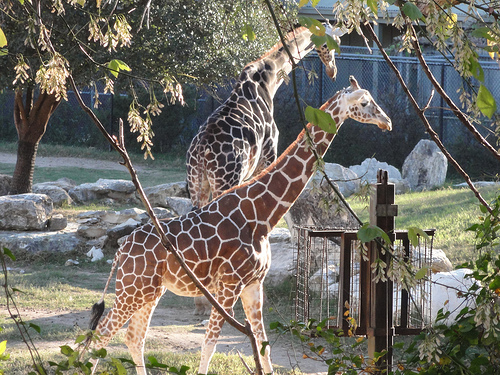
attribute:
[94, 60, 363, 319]
giraffes — walking, in captivity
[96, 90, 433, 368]
giraffe — younger, facing right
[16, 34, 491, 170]
fences — enclosed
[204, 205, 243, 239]
spots — dark brown, light brown, brown, yellow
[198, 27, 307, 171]
giraffe — walking away, walking, mature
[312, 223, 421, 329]
wire — metal, white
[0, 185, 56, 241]
rock — large, grey, part, white, gray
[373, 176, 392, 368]
post — tall, wooden, brown, wood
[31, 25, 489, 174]
fence — silver, chain link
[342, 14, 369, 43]
leaves — green, brown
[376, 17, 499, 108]
branches — brown, wooden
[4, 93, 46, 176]
trunk — brown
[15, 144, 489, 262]
rocks — large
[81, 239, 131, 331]
tail — black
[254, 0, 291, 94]
neck — long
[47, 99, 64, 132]
branch — part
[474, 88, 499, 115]
leaf — part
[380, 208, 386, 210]
nail — part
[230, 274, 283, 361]
leg — white, bottom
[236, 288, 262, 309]
patches — white